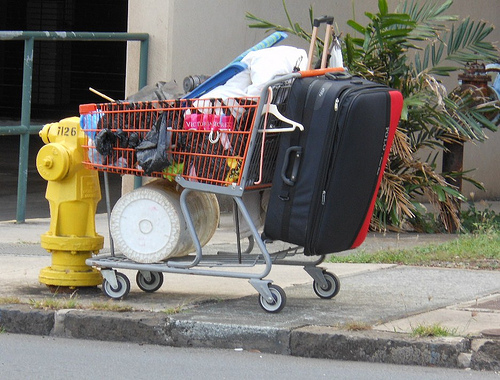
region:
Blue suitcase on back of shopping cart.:
[286, 69, 360, 269]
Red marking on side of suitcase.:
[383, 82, 410, 297]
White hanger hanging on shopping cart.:
[259, 84, 326, 166]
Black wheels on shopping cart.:
[82, 272, 367, 313]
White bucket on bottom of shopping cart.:
[111, 162, 216, 261]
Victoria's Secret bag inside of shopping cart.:
[187, 115, 248, 138]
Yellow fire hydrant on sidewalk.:
[9, 108, 124, 298]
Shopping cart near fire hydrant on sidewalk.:
[101, 125, 395, 325]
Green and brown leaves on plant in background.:
[397, 78, 452, 243]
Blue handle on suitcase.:
[279, 133, 308, 204]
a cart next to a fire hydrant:
[15, 8, 463, 354]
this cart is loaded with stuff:
[96, 58, 371, 296]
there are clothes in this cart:
[73, 68, 278, 183]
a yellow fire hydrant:
[31, 111, 101, 299]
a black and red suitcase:
[269, 10, 422, 268]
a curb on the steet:
[1, 283, 491, 371]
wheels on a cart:
[102, 243, 343, 312]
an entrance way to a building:
[5, 3, 130, 209]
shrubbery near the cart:
[360, 9, 492, 250]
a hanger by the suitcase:
[259, 83, 310, 153]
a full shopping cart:
[54, 14, 404, 309]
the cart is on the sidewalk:
[20, 8, 490, 374]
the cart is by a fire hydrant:
[29, 16, 392, 312]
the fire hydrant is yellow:
[37, 105, 102, 294]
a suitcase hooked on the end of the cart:
[255, 9, 402, 252]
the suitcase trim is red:
[345, 89, 400, 244]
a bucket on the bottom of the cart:
[101, 168, 216, 263]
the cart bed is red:
[76, 94, 272, 193]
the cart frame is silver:
[80, 67, 337, 307]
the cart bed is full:
[72, 51, 264, 180]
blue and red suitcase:
[255, 67, 403, 256]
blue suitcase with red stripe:
[257, 68, 404, 254]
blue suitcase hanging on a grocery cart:
[252, 65, 405, 257]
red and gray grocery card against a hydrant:
[74, 64, 407, 311]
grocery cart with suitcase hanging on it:
[70, 66, 405, 306]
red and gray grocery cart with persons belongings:
[75, 62, 354, 304]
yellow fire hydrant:
[26, 113, 110, 295]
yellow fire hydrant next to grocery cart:
[31, 109, 108, 293]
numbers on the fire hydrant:
[54, 121, 77, 138]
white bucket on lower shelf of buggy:
[105, 174, 223, 268]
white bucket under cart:
[119, 170, 236, 260]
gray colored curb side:
[153, 285, 480, 371]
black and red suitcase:
[271, 72, 441, 299]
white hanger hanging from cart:
[237, 94, 319, 146]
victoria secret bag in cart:
[171, 102, 247, 139]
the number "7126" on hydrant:
[34, 119, 91, 144]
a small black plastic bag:
[114, 131, 193, 168]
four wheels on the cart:
[111, 268, 353, 318]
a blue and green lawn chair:
[183, 37, 272, 66]